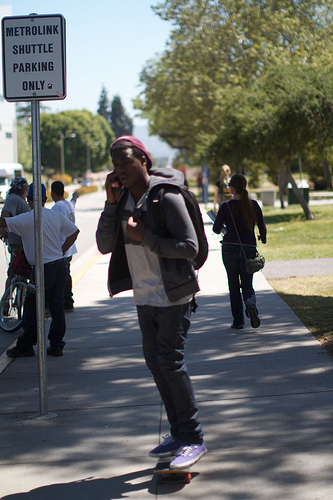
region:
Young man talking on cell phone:
[93, 133, 218, 493]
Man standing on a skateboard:
[85, 132, 217, 496]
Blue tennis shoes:
[145, 425, 213, 466]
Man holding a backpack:
[93, 132, 211, 494]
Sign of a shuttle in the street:
[1, 11, 70, 424]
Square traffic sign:
[0, 14, 75, 102]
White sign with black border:
[0, 10, 72, 102]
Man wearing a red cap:
[90, 135, 239, 486]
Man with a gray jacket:
[93, 128, 224, 490]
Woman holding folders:
[202, 172, 282, 336]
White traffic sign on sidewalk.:
[2, 13, 71, 112]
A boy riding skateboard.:
[91, 127, 218, 486]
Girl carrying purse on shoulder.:
[225, 200, 267, 274]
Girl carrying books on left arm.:
[204, 196, 240, 242]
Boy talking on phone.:
[102, 131, 153, 201]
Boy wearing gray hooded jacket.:
[96, 165, 212, 307]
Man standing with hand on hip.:
[45, 205, 79, 280]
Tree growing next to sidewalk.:
[139, 14, 324, 205]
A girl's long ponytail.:
[232, 180, 254, 228]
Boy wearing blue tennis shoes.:
[146, 427, 207, 467]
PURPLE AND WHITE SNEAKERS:
[147, 429, 207, 468]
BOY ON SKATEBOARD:
[93, 131, 209, 486]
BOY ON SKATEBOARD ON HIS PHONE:
[95, 133, 210, 484]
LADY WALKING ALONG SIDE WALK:
[204, 171, 274, 327]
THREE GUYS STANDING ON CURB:
[3, 162, 78, 362]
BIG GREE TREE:
[134, 49, 332, 223]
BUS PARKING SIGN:
[5, 13, 67, 422]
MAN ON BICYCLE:
[2, 172, 38, 338]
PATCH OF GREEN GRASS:
[249, 203, 331, 259]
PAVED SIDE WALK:
[1, 250, 332, 497]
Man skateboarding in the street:
[89, 132, 242, 485]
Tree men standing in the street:
[3, 173, 84, 363]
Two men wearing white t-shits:
[14, 180, 78, 356]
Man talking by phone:
[89, 134, 211, 489]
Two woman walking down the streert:
[210, 162, 264, 332]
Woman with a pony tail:
[206, 176, 278, 332]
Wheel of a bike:
[0, 273, 29, 338]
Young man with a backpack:
[96, 134, 223, 488]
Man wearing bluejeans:
[88, 131, 224, 492]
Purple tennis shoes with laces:
[149, 429, 224, 469]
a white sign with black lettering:
[4, 12, 77, 111]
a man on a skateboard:
[107, 126, 208, 496]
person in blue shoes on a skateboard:
[144, 418, 217, 482]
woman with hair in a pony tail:
[217, 170, 270, 237]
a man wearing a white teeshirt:
[7, 183, 73, 266]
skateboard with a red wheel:
[141, 436, 200, 497]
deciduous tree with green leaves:
[168, 50, 246, 116]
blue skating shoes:
[135, 428, 211, 471]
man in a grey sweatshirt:
[91, 146, 208, 296]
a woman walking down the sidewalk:
[203, 166, 301, 345]